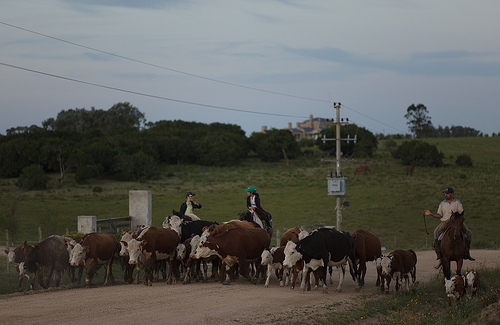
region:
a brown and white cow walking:
[4, 239, 29, 263]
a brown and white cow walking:
[14, 257, 44, 288]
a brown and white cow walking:
[63, 233, 83, 254]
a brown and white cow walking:
[66, 232, 121, 287]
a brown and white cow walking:
[117, 227, 140, 257]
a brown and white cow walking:
[122, 227, 178, 287]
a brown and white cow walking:
[194, 222, 269, 285]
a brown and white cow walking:
[259, 244, 284, 283]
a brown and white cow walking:
[350, 228, 382, 289]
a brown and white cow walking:
[380, 247, 419, 292]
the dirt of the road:
[133, 296, 185, 324]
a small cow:
[371, 251, 424, 288]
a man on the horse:
[434, 187, 476, 224]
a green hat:
[241, 183, 259, 195]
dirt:
[133, 290, 189, 316]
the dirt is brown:
[113, 284, 174, 311]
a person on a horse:
[174, 192, 206, 215]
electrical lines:
[136, 48, 196, 108]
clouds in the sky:
[231, 17, 371, 72]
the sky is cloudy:
[282, 28, 409, 88]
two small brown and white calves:
[438, 264, 485, 311]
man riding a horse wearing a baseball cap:
[421, 183, 468, 277]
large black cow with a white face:
[279, 227, 359, 299]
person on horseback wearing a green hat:
[238, 183, 271, 224]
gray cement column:
[123, 184, 153, 230]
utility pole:
[317, 93, 354, 239]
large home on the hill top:
[255, 112, 336, 144]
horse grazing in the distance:
[350, 164, 371, 180]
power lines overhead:
[0, 19, 335, 126]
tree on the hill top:
[402, 100, 433, 139]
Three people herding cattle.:
[2, 186, 480, 306]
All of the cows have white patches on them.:
[4, 216, 481, 305]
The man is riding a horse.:
[422, 186, 476, 275]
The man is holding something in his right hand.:
[421, 186, 475, 263]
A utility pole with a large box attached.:
[317, 84, 358, 230]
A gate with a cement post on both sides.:
[76, 188, 152, 233]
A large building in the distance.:
[259, 114, 334, 141]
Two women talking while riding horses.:
[172, 185, 272, 228]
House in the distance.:
[258, 116, 340, 150]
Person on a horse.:
[238, 183, 273, 233]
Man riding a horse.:
[420, 182, 473, 274]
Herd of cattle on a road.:
[10, 219, 420, 304]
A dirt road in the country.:
[6, 292, 343, 322]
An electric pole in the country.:
[313, 100, 356, 225]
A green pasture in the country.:
[5, 160, 495, 240]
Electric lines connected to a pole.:
[0, 18, 346, 123]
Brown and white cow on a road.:
[376, 248, 422, 297]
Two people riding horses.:
[171, 185, 278, 229]